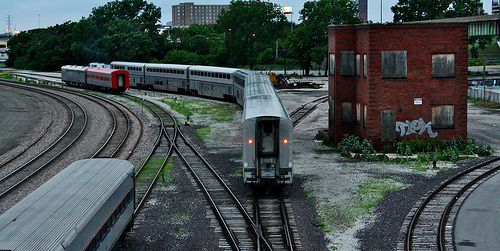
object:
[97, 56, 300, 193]
train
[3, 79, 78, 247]
tracks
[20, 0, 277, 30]
sky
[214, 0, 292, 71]
trees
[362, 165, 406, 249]
gravel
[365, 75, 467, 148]
wall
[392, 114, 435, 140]
graffiti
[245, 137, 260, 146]
dual lights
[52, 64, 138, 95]
train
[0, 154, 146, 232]
train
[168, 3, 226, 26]
tall building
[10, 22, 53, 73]
trees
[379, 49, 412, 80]
boarded windows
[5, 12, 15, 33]
radio tower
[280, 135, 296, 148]
lights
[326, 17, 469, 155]
building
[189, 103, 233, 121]
grass